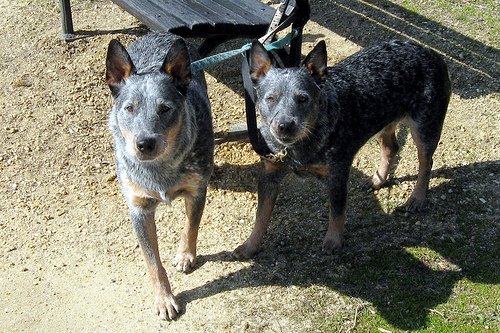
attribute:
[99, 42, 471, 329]
dogs — blue heelers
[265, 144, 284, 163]
clip — gold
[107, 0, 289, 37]
wood bench — black, metal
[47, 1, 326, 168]
bench — wooden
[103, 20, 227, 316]
dog — forward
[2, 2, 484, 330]
dirt — brown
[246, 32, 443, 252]
dog — forward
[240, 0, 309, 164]
leash — black 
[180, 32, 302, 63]
leash — green 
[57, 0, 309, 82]
bench — black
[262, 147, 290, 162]
hook — metal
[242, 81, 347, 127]
eye — lazy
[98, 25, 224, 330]
dog — gray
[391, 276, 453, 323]
grass — green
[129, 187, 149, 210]
dog — tan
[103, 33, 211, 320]
dog — black, gray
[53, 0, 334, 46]
bench — black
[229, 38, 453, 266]
dog — black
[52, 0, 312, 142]
bench — black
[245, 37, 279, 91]
ear — up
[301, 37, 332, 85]
ear — up